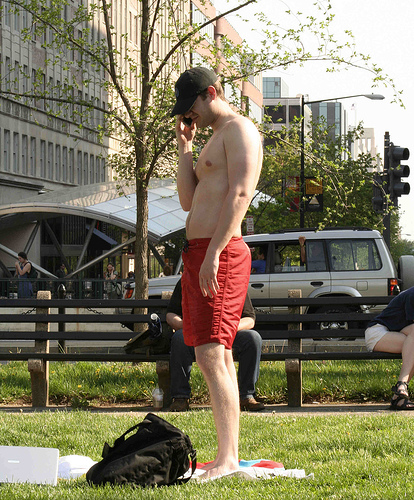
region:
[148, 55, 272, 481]
man wearing red shorts talking on cell phone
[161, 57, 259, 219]
man with black hat talking on cellphone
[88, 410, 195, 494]
black bag by man's feet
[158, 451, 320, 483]
man is standing on a towel in bare feet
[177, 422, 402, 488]
towel is lying on green grass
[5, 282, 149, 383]
wooden bench is to the man's right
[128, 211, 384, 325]
suv on street in background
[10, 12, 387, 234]
trees are beginning to grow leaves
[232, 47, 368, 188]
tall buildings in the background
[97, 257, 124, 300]
woman talking on cell phone in front of building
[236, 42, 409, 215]
a few tall buildings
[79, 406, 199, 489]
a plain black bag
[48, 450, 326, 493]
a towel on the grass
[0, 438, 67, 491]
a name brand silver laptop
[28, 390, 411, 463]
a path by the grass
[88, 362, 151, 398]
some yellow wild flowers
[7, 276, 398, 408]
a long wood and stone bench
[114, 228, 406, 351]
a large silver suv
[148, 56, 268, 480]
a man in bright red shorts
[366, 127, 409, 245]
a black metal traffic light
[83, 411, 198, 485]
black nylon bag on grass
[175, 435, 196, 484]
black strap on bag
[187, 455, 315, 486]
towel under man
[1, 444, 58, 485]
gray laptop on grass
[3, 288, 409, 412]
park bench behind man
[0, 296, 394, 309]
black wooden slat on bench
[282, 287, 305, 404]
concrete support for bench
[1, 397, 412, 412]
concrete sidewalk under bench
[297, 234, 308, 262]
arm outside vehicle window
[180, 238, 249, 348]
man wearing red shorts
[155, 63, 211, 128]
man wears black hat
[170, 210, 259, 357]
man wears red shorts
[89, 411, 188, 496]
man has black backpack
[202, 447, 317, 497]
man stands on towel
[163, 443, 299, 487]
towel is red and blue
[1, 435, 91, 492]
white object left of backpack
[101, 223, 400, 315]
grey van behind man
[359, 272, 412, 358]
person sitting on bench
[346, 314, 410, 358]
person wears white shorts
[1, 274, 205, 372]
brown bench behind man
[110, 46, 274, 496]
A man talking on a phone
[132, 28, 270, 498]
A man not wearing a shirt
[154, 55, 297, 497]
A man wearing red shorts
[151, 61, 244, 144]
A man wearing a baseball cap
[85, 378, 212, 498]
A black backpack on the ground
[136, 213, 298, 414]
A person sitting on a bench behing the man in red shorts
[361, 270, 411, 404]
A person wearing white shorts sitting on a bench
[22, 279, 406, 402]
A park bench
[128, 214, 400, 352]
A vehicle in the street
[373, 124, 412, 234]
A stoplight on a pole